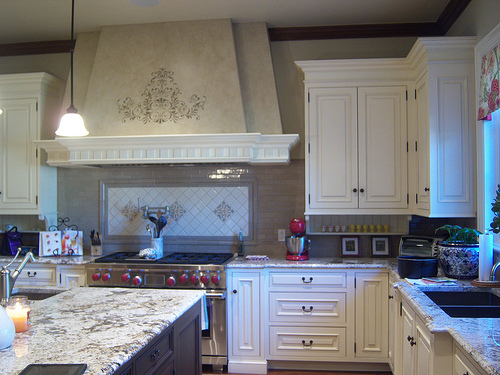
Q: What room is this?
A: It is a kitchen.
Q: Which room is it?
A: It is a kitchen.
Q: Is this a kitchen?
A: Yes, it is a kitchen.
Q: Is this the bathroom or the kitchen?
A: It is the kitchen.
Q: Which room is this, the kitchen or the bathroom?
A: It is the kitchen.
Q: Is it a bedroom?
A: No, it is a kitchen.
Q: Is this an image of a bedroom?
A: No, the picture is showing a kitchen.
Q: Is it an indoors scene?
A: Yes, it is indoors.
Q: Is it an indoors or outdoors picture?
A: It is indoors.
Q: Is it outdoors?
A: No, it is indoors.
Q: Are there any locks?
A: No, there are no locks.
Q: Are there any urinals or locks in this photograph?
A: No, there are no locks or urinals.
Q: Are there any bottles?
A: No, there are no bottles.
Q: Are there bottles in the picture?
A: No, there are no bottles.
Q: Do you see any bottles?
A: No, there are no bottles.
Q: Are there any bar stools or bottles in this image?
A: No, there are no bottles or bar stools.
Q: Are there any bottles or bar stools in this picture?
A: No, there are no bottles or bar stools.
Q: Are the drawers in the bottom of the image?
A: Yes, the drawers are in the bottom of the image.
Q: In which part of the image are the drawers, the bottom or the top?
A: The drawers are in the bottom of the image.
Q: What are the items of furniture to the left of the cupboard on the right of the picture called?
A: The pieces of furniture are drawers.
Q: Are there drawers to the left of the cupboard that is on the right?
A: Yes, there are drawers to the left of the cupboard.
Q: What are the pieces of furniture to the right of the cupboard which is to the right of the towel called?
A: The pieces of furniture are drawers.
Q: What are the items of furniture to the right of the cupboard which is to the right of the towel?
A: The pieces of furniture are drawers.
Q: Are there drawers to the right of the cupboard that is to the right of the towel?
A: Yes, there are drawers to the right of the cupboard.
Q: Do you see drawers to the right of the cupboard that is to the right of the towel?
A: Yes, there are drawers to the right of the cupboard.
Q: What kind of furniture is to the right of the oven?
A: The pieces of furniture are drawers.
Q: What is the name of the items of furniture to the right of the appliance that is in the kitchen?
A: The pieces of furniture are drawers.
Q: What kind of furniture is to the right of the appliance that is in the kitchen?
A: The pieces of furniture are drawers.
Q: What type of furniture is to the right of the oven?
A: The pieces of furniture are drawers.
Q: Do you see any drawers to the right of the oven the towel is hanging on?
A: Yes, there are drawers to the right of the oven.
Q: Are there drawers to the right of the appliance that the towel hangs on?
A: Yes, there are drawers to the right of the oven.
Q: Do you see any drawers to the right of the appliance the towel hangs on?
A: Yes, there are drawers to the right of the oven.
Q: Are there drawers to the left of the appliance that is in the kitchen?
A: No, the drawers are to the right of the oven.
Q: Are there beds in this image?
A: No, there are no beds.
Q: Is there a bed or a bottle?
A: No, there are no beds or bottles.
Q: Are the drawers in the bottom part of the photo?
A: Yes, the drawers are in the bottom of the image.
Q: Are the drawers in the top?
A: No, the drawers are in the bottom of the image.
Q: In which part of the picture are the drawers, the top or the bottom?
A: The drawers are in the bottom of the image.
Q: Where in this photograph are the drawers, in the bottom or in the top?
A: The drawers are in the bottom of the image.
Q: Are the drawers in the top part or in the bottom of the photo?
A: The drawers are in the bottom of the image.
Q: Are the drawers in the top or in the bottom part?
A: The drawers are in the bottom of the image.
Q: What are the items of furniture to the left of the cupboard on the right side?
A: The pieces of furniture are drawers.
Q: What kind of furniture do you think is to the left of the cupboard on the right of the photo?
A: The pieces of furniture are drawers.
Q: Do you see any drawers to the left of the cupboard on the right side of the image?
A: Yes, there are drawers to the left of the cupboard.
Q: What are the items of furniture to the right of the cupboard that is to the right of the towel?
A: The pieces of furniture are drawers.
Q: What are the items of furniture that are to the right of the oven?
A: The pieces of furniture are drawers.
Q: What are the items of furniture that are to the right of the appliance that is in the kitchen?
A: The pieces of furniture are drawers.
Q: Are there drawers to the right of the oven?
A: Yes, there are drawers to the right of the oven.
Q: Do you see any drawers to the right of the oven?
A: Yes, there are drawers to the right of the oven.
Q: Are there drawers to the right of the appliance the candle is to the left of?
A: Yes, there are drawers to the right of the oven.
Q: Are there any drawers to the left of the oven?
A: No, the drawers are to the right of the oven.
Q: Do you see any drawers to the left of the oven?
A: No, the drawers are to the right of the oven.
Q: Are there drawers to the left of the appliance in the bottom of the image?
A: No, the drawers are to the right of the oven.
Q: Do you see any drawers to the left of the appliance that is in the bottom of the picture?
A: No, the drawers are to the right of the oven.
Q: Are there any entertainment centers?
A: No, there are no entertainment centers.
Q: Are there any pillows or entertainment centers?
A: No, there are no entertainment centers or pillows.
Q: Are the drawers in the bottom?
A: Yes, the drawers are in the bottom of the image.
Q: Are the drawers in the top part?
A: No, the drawers are in the bottom of the image.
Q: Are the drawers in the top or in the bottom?
A: The drawers are in the bottom of the image.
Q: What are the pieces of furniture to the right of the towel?
A: The pieces of furniture are drawers.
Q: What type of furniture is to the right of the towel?
A: The pieces of furniture are drawers.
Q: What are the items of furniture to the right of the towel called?
A: The pieces of furniture are drawers.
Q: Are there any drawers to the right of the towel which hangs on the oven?
A: Yes, there are drawers to the right of the towel.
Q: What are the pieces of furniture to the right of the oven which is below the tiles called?
A: The pieces of furniture are drawers.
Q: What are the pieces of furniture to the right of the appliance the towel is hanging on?
A: The pieces of furniture are drawers.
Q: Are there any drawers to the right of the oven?
A: Yes, there are drawers to the right of the oven.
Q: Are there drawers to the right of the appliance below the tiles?
A: Yes, there are drawers to the right of the oven.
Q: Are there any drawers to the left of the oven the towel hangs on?
A: No, the drawers are to the right of the oven.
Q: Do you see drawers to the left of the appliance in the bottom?
A: No, the drawers are to the right of the oven.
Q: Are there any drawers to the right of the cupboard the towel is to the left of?
A: Yes, there are drawers to the right of the cupboard.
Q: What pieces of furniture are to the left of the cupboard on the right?
A: The pieces of furniture are drawers.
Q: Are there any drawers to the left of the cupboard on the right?
A: Yes, there are drawers to the left of the cupboard.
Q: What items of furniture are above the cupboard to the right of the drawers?
A: The pieces of furniture are cabinets.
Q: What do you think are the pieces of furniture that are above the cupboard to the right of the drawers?
A: The pieces of furniture are cabinets.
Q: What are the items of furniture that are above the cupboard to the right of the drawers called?
A: The pieces of furniture are cabinets.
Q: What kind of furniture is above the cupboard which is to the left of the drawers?
A: The pieces of furniture are cabinets.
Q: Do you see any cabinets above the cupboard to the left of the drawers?
A: Yes, there are cabinets above the cupboard.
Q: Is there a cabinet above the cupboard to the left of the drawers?
A: Yes, there are cabinets above the cupboard.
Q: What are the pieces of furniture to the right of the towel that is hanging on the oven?
A: The pieces of furniture are cabinets.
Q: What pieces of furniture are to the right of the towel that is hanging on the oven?
A: The pieces of furniture are cabinets.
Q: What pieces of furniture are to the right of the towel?
A: The pieces of furniture are cabinets.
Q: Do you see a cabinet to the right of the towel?
A: Yes, there are cabinets to the right of the towel.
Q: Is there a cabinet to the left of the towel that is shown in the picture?
A: No, the cabinets are to the right of the towel.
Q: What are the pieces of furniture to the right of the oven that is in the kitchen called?
A: The pieces of furniture are cabinets.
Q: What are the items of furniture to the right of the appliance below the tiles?
A: The pieces of furniture are cabinets.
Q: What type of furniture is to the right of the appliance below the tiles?
A: The pieces of furniture are cabinets.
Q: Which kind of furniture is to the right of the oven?
A: The pieces of furniture are cabinets.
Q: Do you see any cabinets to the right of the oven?
A: Yes, there are cabinets to the right of the oven.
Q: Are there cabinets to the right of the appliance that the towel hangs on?
A: Yes, there are cabinets to the right of the oven.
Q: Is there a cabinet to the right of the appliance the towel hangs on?
A: Yes, there are cabinets to the right of the oven.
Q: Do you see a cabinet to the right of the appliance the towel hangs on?
A: Yes, there are cabinets to the right of the oven.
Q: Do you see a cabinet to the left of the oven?
A: No, the cabinets are to the right of the oven.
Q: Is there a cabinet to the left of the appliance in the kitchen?
A: No, the cabinets are to the right of the oven.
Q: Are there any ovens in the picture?
A: Yes, there is an oven.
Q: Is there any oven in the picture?
A: Yes, there is an oven.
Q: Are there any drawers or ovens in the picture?
A: Yes, there is an oven.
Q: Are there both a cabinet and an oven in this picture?
A: Yes, there are both an oven and a cabinet.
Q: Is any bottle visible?
A: No, there are no bottles.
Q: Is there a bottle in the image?
A: No, there are no bottles.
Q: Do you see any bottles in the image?
A: No, there are no bottles.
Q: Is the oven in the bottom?
A: Yes, the oven is in the bottom of the image.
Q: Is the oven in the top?
A: No, the oven is in the bottom of the image.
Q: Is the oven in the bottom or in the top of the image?
A: The oven is in the bottom of the image.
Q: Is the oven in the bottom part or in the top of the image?
A: The oven is in the bottom of the image.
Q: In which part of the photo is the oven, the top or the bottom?
A: The oven is in the bottom of the image.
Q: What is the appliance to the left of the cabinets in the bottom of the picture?
A: The appliance is an oven.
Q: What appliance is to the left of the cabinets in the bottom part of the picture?
A: The appliance is an oven.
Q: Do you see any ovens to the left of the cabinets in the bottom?
A: Yes, there is an oven to the left of the cabinets.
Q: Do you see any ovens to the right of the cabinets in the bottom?
A: No, the oven is to the left of the cabinets.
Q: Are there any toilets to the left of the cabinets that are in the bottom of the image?
A: No, there is an oven to the left of the cabinets.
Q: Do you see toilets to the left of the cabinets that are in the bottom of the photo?
A: No, there is an oven to the left of the cabinets.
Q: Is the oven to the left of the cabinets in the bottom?
A: Yes, the oven is to the left of the cabinets.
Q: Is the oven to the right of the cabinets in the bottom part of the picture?
A: No, the oven is to the left of the cabinets.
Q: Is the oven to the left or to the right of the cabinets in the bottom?
A: The oven is to the left of the cabinets.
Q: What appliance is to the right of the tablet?
A: The appliance is an oven.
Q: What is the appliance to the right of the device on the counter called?
A: The appliance is an oven.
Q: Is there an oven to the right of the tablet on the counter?
A: Yes, there is an oven to the right of the tablet.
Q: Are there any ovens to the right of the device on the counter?
A: Yes, there is an oven to the right of the tablet.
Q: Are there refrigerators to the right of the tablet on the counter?
A: No, there is an oven to the right of the tablet.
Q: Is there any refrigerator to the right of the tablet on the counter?
A: No, there is an oven to the right of the tablet.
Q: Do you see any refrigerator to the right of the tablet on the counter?
A: No, there is an oven to the right of the tablet.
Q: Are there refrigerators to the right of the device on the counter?
A: No, there is an oven to the right of the tablet.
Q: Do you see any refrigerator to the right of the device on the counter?
A: No, there is an oven to the right of the tablet.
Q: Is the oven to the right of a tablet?
A: Yes, the oven is to the right of a tablet.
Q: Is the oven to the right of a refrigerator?
A: No, the oven is to the right of a tablet.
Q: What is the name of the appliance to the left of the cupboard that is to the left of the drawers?
A: The appliance is an oven.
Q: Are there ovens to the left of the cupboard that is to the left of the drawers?
A: Yes, there is an oven to the left of the cupboard.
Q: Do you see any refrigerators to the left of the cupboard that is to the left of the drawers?
A: No, there is an oven to the left of the cupboard.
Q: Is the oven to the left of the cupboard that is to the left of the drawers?
A: Yes, the oven is to the left of the cupboard.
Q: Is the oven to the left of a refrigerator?
A: No, the oven is to the left of the cupboard.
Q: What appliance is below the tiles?
A: The appliance is an oven.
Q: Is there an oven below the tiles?
A: Yes, there is an oven below the tiles.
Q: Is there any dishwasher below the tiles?
A: No, there is an oven below the tiles.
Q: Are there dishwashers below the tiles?
A: No, there is an oven below the tiles.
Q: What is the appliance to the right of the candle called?
A: The appliance is an oven.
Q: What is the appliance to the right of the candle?
A: The appliance is an oven.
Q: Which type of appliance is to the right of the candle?
A: The appliance is an oven.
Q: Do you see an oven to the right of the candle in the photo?
A: Yes, there is an oven to the right of the candle.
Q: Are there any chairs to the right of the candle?
A: No, there is an oven to the right of the candle.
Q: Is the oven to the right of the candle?
A: Yes, the oven is to the right of the candle.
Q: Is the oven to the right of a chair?
A: No, the oven is to the right of the candle.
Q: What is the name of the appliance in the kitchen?
A: The appliance is an oven.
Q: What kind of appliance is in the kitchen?
A: The appliance is an oven.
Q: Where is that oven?
A: The oven is in the kitchen.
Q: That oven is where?
A: The oven is in the kitchen.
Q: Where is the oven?
A: The oven is in the kitchen.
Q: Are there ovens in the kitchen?
A: Yes, there is an oven in the kitchen.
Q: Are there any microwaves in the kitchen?
A: No, there is an oven in the kitchen.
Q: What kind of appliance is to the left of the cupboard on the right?
A: The appliance is an oven.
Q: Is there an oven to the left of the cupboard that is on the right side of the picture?
A: Yes, there is an oven to the left of the cupboard.